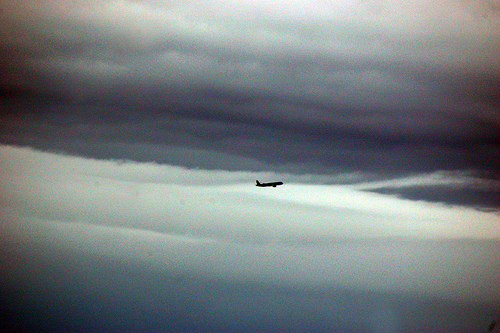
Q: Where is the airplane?
A: In the sky.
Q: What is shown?
A: An airplane.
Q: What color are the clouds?
A: White.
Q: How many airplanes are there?
A: One.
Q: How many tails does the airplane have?
A: One.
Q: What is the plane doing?
A: Flying in the sky.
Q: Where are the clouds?
A: In the sky.